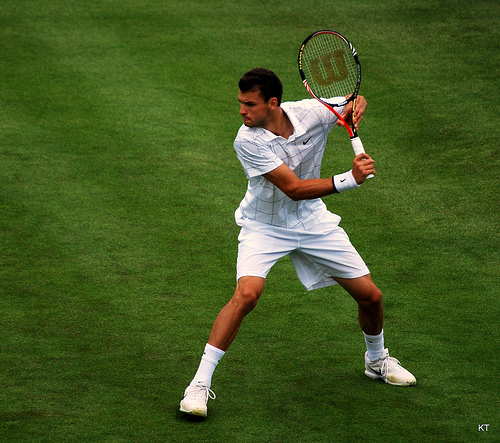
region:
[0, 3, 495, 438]
the grass is striped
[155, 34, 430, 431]
the man is playing tennis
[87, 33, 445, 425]
the man is turned sideways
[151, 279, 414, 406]
the man's socks are white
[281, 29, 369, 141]
the tennis racket is red and blac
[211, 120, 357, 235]
the shirt is full of squares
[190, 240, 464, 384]
the man's knees are bent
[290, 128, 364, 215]
nike is the brand name of man's clothes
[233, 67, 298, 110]
the man's hair is brown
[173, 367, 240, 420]
man's shoelaces are tied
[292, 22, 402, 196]
wilson brand tennis racket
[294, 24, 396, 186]
tennis racket with white tape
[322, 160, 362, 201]
white wrist bands with logo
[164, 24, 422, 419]
man playing tennis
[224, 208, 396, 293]
white tennis shorts on man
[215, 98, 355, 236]
white and striped polo shirt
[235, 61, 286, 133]
man with determined look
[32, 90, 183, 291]
grass mowed in stripe pattern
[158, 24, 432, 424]
man in defensive position with tennis racket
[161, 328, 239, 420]
white tennis shoes and white socks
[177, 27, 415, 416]
tennis player in white shorts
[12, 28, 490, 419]
man playing a game of tennis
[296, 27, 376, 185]
black and red tennis racket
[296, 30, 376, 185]
racket in tennis player's hands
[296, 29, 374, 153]
Wilson's red and black tennis racket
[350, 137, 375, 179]
white grip handle on tennis racket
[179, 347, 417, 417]
Nike tennis shoes on player's feet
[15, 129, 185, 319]
green grass on the tennis court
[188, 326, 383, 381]
white socks on the man's feet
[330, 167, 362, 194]
white Nike sweat band on tennis player's wrist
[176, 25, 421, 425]
man holding tennis racket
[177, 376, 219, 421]
white tennis shoe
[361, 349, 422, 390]
white tennis shoe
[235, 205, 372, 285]
white shorts on man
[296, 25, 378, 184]
red and black tennis racket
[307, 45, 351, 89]
letter "W" on tennis racket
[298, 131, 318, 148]
black Nike logo on white shirt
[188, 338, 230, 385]
white sock of man's right foot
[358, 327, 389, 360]
white sock of man's left foot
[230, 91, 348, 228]
white shirt of man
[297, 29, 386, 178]
a red and black tennis racquet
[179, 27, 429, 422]
a man swinging a tennis racket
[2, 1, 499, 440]
a green lawn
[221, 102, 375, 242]
a white shirt with squared stripes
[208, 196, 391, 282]
white shorts on a man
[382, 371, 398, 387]
a stain on the side of a shoe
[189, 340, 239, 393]
a white sock on a man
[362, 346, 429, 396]
a white Nike tennis shoe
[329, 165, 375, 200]
a white Nike wristband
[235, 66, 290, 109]
dark hair on a man's head